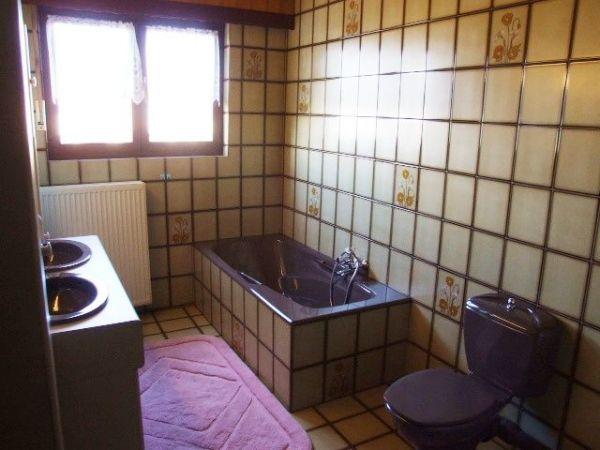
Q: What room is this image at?
A: It is at the bathroom.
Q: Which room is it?
A: It is a bathroom.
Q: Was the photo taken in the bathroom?
A: Yes, it was taken in the bathroom.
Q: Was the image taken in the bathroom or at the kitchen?
A: It was taken at the bathroom.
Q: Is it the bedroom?
A: No, it is the bathroom.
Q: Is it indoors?
A: Yes, it is indoors.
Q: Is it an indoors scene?
A: Yes, it is indoors.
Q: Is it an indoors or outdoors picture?
A: It is indoors.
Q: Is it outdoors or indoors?
A: It is indoors.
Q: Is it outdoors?
A: No, it is indoors.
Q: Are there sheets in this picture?
A: No, there are no sheets.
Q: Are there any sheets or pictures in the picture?
A: No, there are no sheets or pictures.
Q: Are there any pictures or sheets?
A: No, there are no sheets or pictures.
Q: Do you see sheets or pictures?
A: No, there are no sheets or pictures.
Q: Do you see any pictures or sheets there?
A: No, there are no sheets or pictures.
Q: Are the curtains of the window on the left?
A: Yes, the curtains are on the left of the image.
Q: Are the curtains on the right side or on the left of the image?
A: The curtains are on the left of the image.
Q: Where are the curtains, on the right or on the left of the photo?
A: The curtains are on the left of the image.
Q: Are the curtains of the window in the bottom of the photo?
A: No, the curtains are in the top of the image.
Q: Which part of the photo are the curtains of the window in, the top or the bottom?
A: The curtains are in the top of the image.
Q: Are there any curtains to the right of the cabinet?
A: Yes, there are curtains to the right of the cabinet.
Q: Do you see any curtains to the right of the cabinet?
A: Yes, there are curtains to the right of the cabinet.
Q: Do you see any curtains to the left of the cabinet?
A: No, the curtains are to the right of the cabinet.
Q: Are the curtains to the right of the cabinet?
A: Yes, the curtains are to the right of the cabinet.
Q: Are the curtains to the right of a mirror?
A: No, the curtains are to the right of the cabinet.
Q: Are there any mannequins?
A: No, there are no mannequins.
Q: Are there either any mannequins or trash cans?
A: No, there are no mannequins or trash cans.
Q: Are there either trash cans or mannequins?
A: No, there are no mannequins or trash cans.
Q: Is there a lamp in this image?
A: No, there are no lamps.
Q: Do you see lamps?
A: No, there are no lamps.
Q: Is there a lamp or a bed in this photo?
A: No, there are no lamps or beds.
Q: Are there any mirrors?
A: No, there are no mirrors.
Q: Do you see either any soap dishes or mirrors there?
A: No, there are no mirrors or soap dishes.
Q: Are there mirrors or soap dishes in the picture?
A: No, there are no mirrors or soap dishes.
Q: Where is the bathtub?
A: The bathtub is in the bathroom.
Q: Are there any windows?
A: Yes, there is a window.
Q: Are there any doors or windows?
A: Yes, there is a window.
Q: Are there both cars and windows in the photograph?
A: No, there is a window but no cars.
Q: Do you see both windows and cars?
A: No, there is a window but no cars.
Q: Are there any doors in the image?
A: No, there are no doors.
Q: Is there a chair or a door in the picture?
A: No, there are no doors or chairs.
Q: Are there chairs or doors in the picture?
A: No, there are no doors or chairs.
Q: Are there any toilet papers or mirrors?
A: No, there are no mirrors or toilet papers.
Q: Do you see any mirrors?
A: No, there are no mirrors.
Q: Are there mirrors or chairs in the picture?
A: No, there are no mirrors or chairs.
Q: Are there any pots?
A: No, there are no pots.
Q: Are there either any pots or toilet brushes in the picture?
A: No, there are no pots or toilet brushes.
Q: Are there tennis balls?
A: No, there are no tennis balls.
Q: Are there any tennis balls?
A: No, there are no tennis balls.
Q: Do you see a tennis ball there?
A: No, there are no tennis balls.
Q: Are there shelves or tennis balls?
A: No, there are no tennis balls or shelves.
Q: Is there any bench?
A: No, there are no benches.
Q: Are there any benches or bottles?
A: No, there are no benches or bottles.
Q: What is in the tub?
A: The faucet is in the tub.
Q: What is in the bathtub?
A: The faucet is in the tub.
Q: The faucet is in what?
A: The faucet is in the bathtub.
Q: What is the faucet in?
A: The faucet is in the bathtub.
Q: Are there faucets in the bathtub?
A: Yes, there is a faucet in the bathtub.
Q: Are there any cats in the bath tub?
A: No, there is a faucet in the bath tub.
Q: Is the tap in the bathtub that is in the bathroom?
A: Yes, the tap is in the bathtub.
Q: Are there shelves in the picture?
A: No, there are no shelves.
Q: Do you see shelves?
A: No, there are no shelves.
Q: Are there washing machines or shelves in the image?
A: No, there are no shelves or washing machines.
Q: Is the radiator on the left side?
A: Yes, the radiator is on the left of the image.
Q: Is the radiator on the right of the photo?
A: No, the radiator is on the left of the image.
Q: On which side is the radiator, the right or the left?
A: The radiator is on the left of the image.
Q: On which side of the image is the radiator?
A: The radiator is on the left of the image.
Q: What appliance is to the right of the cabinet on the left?
A: The appliance is a radiator.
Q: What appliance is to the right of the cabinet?
A: The appliance is a radiator.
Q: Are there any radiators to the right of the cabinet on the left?
A: Yes, there is a radiator to the right of the cabinet.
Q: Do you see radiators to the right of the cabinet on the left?
A: Yes, there is a radiator to the right of the cabinet.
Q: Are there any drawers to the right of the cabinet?
A: No, there is a radiator to the right of the cabinet.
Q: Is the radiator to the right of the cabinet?
A: Yes, the radiator is to the right of the cabinet.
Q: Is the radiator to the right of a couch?
A: No, the radiator is to the right of the cabinet.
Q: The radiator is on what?
A: The radiator is on the wall.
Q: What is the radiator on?
A: The radiator is on the wall.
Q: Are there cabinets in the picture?
A: Yes, there is a cabinet.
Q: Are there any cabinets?
A: Yes, there is a cabinet.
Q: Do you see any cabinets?
A: Yes, there is a cabinet.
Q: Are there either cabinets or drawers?
A: Yes, there is a cabinet.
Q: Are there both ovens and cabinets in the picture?
A: No, there is a cabinet but no ovens.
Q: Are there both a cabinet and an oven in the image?
A: No, there is a cabinet but no ovens.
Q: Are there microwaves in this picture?
A: No, there are no microwaves.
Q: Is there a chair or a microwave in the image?
A: No, there are no microwaves or chairs.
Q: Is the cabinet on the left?
A: Yes, the cabinet is on the left of the image.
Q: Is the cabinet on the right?
A: No, the cabinet is on the left of the image.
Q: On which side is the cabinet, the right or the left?
A: The cabinet is on the left of the image.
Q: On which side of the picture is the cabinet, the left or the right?
A: The cabinet is on the left of the image.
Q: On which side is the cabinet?
A: The cabinet is on the left of the image.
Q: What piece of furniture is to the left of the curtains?
A: The piece of furniture is a cabinet.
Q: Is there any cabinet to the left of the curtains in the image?
A: Yes, there is a cabinet to the left of the curtains.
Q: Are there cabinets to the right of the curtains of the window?
A: No, the cabinet is to the left of the curtains.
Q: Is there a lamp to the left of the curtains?
A: No, there is a cabinet to the left of the curtains.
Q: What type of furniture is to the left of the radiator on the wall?
A: The piece of furniture is a cabinet.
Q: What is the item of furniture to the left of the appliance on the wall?
A: The piece of furniture is a cabinet.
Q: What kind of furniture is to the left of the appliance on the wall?
A: The piece of furniture is a cabinet.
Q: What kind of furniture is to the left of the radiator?
A: The piece of furniture is a cabinet.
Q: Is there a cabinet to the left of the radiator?
A: Yes, there is a cabinet to the left of the radiator.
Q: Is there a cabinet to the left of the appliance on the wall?
A: Yes, there is a cabinet to the left of the radiator.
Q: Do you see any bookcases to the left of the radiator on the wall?
A: No, there is a cabinet to the left of the radiator.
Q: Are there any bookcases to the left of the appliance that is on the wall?
A: No, there is a cabinet to the left of the radiator.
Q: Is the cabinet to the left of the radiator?
A: Yes, the cabinet is to the left of the radiator.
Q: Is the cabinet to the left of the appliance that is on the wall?
A: Yes, the cabinet is to the left of the radiator.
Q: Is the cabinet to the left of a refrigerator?
A: No, the cabinet is to the left of the radiator.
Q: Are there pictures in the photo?
A: No, there are no pictures.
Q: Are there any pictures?
A: No, there are no pictures.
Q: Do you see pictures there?
A: No, there are no pictures.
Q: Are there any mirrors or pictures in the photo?
A: No, there are no pictures or mirrors.